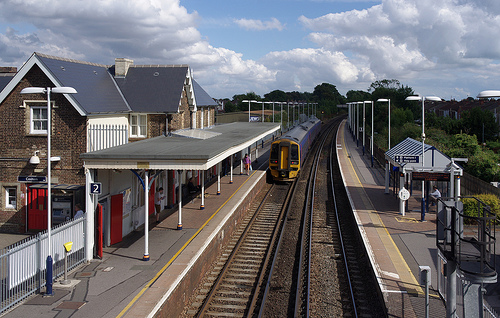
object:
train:
[267, 110, 345, 183]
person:
[241, 151, 251, 177]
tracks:
[191, 183, 293, 317]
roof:
[37, 54, 130, 116]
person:
[426, 185, 444, 209]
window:
[30, 109, 52, 130]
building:
[0, 51, 220, 249]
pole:
[199, 172, 206, 209]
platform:
[0, 145, 272, 318]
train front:
[267, 137, 302, 183]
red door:
[26, 186, 46, 230]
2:
[89, 183, 102, 195]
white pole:
[177, 169, 182, 228]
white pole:
[215, 163, 222, 193]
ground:
[0, 120, 465, 317]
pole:
[144, 172, 152, 263]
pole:
[227, 156, 232, 185]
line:
[113, 158, 271, 318]